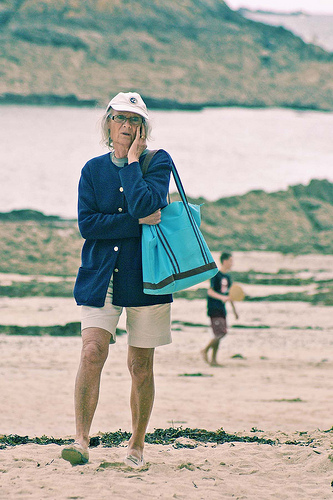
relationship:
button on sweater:
[117, 181, 130, 196] [71, 151, 176, 298]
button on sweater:
[117, 201, 124, 215] [71, 151, 176, 298]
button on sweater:
[111, 242, 123, 251] [71, 151, 176, 298]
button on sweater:
[112, 264, 117, 278] [71, 151, 176, 298]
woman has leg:
[78, 75, 190, 218] [71, 282, 123, 450]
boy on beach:
[199, 250, 238, 366] [0, 252, 333, 498]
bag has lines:
[140, 148, 218, 294] [133, 193, 222, 288]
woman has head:
[78, 75, 190, 218] [86, 76, 182, 177]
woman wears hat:
[78, 75, 190, 218] [88, 73, 172, 128]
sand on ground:
[2, 253, 332, 499] [2, 291, 311, 498]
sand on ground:
[2, 253, 332, 499] [0, 179, 332, 497]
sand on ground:
[2, 439, 329, 497] [1, 272, 330, 499]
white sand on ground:
[2, 271, 332, 498] [1, 272, 330, 499]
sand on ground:
[206, 462, 312, 486] [15, 471, 328, 499]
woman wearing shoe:
[78, 75, 190, 218] [109, 448, 157, 473]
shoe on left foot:
[109, 448, 157, 473] [118, 437, 148, 468]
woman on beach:
[78, 75, 190, 218] [0, 146, 325, 344]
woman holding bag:
[78, 75, 190, 218] [133, 210, 212, 297]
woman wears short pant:
[78, 75, 190, 218] [79, 261, 171, 349]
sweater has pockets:
[72, 147, 173, 309] [70, 259, 155, 307]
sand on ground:
[63, 456, 173, 488] [4, 337, 292, 498]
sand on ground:
[249, 382, 279, 413] [2, 291, 311, 498]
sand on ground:
[2, 439, 329, 497] [0, 246, 333, 499]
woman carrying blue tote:
[78, 75, 190, 218] [135, 141, 220, 294]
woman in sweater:
[78, 75, 190, 218] [72, 147, 173, 309]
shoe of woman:
[59, 443, 88, 464] [50, 73, 231, 406]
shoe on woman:
[59, 443, 88, 464] [78, 75, 190, 218]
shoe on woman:
[109, 448, 157, 473] [52, 108, 193, 451]